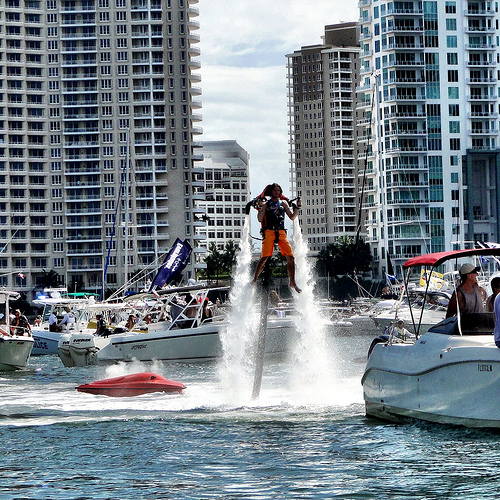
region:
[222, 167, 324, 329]
jet skier in the water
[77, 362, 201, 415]
red jet ski in water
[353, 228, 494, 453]
boat in the water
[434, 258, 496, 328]
man steering the boat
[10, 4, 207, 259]
buildings along the shore line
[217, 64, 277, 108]
white clouds in the sky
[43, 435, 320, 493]
blue waters by the boats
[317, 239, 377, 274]
green leaves on a tree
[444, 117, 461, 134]
window of a building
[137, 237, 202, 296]
blue banner on a boat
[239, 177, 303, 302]
person up in the air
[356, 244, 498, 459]
white boat with people on it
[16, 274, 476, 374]
many white boats on the water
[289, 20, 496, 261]
tall buildings with windows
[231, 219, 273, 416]
white splashed water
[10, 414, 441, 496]
ripples on blue water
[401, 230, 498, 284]
maroon colored hood on boat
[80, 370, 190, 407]
red object on the water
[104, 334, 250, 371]
black stripes on a white boat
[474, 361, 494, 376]
small black lettering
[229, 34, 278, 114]
clouds in the sky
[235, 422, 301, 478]
water below the person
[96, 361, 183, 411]
red thing in the water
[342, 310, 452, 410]
boat next to person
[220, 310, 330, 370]
water falling off man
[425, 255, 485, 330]
man inside the boat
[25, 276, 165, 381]
boats in the background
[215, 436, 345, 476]
ripples in the water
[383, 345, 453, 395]
side of the boat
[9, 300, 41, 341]
person in the background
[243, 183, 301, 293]
person using a water powered jet pack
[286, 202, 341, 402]
left exhaust nozzle with water exhaust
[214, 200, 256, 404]
right exhaust nozzle with water exhaust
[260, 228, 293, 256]
bright orange swimming shorts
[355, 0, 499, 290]
green and white high rise building has many balconies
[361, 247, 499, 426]
white boat with a red roof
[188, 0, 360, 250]
clouds in the sky are white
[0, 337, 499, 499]
blue ripples in the harbor waters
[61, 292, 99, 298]
turquoise roof of a distant boat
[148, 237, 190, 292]
dark blue and white banner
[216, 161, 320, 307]
lady in the air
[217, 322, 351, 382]
water in the air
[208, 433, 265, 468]
ripples in the water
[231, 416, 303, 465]
water below the lady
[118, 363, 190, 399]
red object next to lady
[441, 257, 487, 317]
man with a hat on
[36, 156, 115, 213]
building in the background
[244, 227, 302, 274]
orange shorts on person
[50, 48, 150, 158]
many windows on building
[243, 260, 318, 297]
legs of the lady